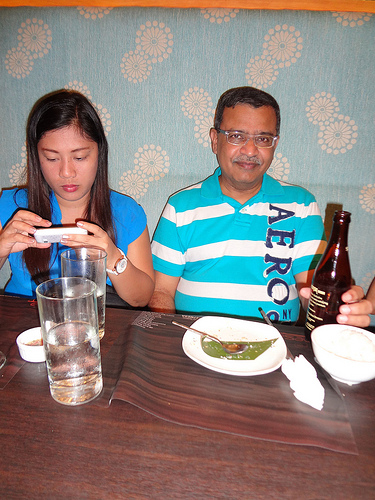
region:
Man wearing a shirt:
[144, 164, 347, 323]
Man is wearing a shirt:
[146, 162, 331, 328]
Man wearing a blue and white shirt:
[147, 161, 336, 328]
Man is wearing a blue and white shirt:
[145, 163, 334, 321]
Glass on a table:
[25, 272, 113, 409]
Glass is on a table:
[35, 272, 110, 409]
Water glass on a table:
[33, 274, 110, 407]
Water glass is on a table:
[36, 274, 105, 409]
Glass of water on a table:
[31, 275, 109, 407]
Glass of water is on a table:
[35, 272, 108, 409]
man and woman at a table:
[7, 61, 362, 320]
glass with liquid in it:
[30, 270, 103, 411]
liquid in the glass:
[49, 333, 95, 388]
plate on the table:
[172, 306, 285, 379]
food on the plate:
[199, 335, 277, 362]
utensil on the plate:
[167, 302, 248, 365]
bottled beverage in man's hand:
[302, 207, 344, 331]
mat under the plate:
[106, 306, 370, 449]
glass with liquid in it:
[52, 250, 111, 335]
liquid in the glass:
[69, 286, 102, 332]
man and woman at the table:
[0, 75, 370, 496]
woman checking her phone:
[1, 71, 155, 305]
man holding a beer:
[148, 82, 368, 329]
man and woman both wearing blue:
[0, 82, 372, 329]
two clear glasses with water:
[36, 232, 112, 406]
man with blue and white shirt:
[152, 77, 354, 325]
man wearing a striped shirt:
[158, 84, 347, 324]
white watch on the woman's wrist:
[101, 247, 134, 278]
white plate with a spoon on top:
[166, 302, 288, 384]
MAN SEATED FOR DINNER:
[152, 84, 362, 317]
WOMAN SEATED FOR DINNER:
[5, 85, 152, 310]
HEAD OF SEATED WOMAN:
[23, 90, 110, 200]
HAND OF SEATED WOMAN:
[1, 206, 47, 251]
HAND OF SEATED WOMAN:
[62, 214, 113, 263]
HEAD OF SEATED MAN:
[207, 82, 288, 190]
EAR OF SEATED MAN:
[205, 126, 220, 153]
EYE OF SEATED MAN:
[224, 130, 247, 140]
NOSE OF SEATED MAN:
[241, 135, 258, 162]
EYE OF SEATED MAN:
[254, 133, 276, 148]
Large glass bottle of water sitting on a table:
[28, 275, 105, 412]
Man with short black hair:
[208, 80, 288, 189]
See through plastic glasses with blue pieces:
[217, 122, 278, 154]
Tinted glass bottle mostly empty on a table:
[300, 197, 356, 331]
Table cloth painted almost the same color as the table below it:
[124, 325, 199, 444]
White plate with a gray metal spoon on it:
[169, 302, 278, 392]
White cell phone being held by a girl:
[25, 204, 89, 255]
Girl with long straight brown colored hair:
[15, 83, 127, 222]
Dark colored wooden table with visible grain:
[16, 401, 367, 495]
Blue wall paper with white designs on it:
[99, 14, 180, 82]